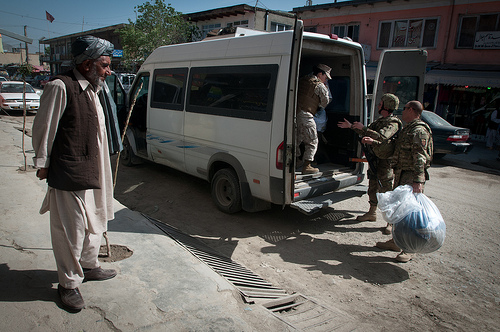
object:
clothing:
[32, 74, 124, 290]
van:
[118, 30, 429, 215]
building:
[287, 0, 499, 149]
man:
[31, 35, 124, 309]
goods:
[375, 183, 445, 253]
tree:
[113, 0, 205, 73]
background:
[0, 0, 499, 156]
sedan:
[418, 109, 473, 159]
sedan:
[0, 80, 42, 112]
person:
[375, 101, 434, 262]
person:
[337, 93, 402, 234]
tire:
[210, 165, 242, 214]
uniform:
[372, 118, 434, 193]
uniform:
[350, 116, 402, 206]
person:
[296, 63, 332, 173]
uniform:
[295, 73, 332, 161]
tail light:
[274, 139, 288, 170]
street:
[0, 81, 499, 331]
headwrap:
[67, 35, 115, 67]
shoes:
[56, 282, 86, 309]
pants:
[50, 186, 103, 288]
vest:
[47, 71, 124, 191]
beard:
[84, 61, 107, 92]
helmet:
[380, 93, 400, 110]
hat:
[314, 63, 332, 80]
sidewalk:
[0, 122, 295, 331]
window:
[373, 19, 391, 50]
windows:
[150, 66, 192, 111]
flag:
[46, 10, 56, 23]